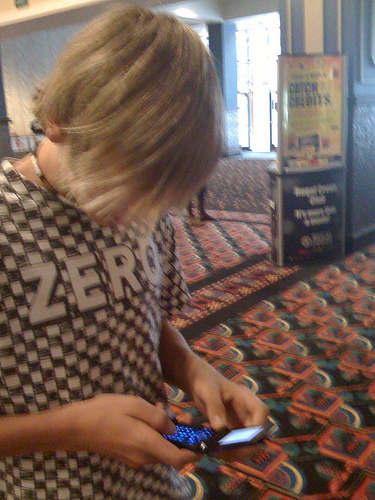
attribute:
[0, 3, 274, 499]
boy — blonde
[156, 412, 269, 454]
cell phone — open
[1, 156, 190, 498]
shirt — black, white, checkered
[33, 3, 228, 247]
hair — blonde, long, blond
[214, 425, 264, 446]
screen — lit, blue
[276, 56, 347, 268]
poster — advertising, black, yellow, white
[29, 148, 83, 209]
necklace — black brown white, beaded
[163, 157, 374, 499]
carpet — flooring, multicolored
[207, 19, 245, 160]
molding — green, black, blue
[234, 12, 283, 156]
entry — open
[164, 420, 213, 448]
keypad — blue, lit